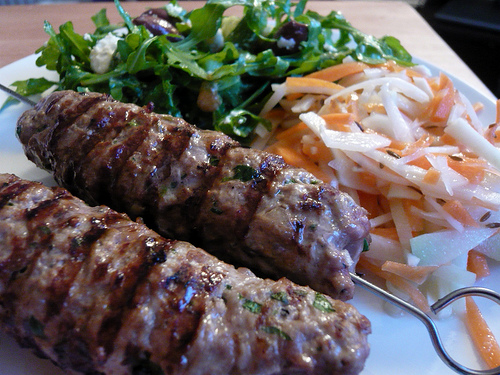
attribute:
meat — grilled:
[16, 89, 371, 299]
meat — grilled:
[0, 172, 372, 373]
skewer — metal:
[350, 273, 499, 373]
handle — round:
[429, 285, 499, 374]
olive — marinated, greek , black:
[132, 5, 183, 35]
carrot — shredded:
[284, 74, 342, 95]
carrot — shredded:
[308, 60, 368, 81]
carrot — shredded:
[274, 111, 353, 141]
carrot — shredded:
[421, 70, 456, 126]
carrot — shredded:
[441, 196, 474, 225]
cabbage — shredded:
[322, 76, 428, 103]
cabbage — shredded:
[378, 82, 412, 146]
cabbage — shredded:
[444, 116, 499, 171]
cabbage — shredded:
[329, 155, 377, 193]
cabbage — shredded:
[410, 227, 499, 268]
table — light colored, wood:
[0, 0, 496, 103]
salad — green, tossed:
[1, 0, 411, 138]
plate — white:
[0, 26, 499, 373]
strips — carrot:
[312, 93, 458, 219]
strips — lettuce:
[124, 13, 251, 76]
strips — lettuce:
[150, 25, 310, 78]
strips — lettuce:
[131, 32, 254, 82]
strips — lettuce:
[119, 15, 308, 107]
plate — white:
[22, 12, 484, 359]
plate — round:
[4, 9, 446, 372]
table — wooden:
[11, 2, 86, 52]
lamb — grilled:
[43, 96, 337, 293]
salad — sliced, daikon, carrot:
[237, 51, 465, 222]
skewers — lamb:
[5, 69, 484, 361]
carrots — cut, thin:
[303, 77, 476, 223]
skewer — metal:
[0, 58, 448, 372]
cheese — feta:
[78, 22, 162, 88]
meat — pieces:
[0, 67, 310, 371]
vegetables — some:
[304, 41, 484, 202]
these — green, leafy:
[88, 15, 238, 97]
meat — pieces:
[33, 84, 374, 370]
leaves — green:
[119, 6, 290, 97]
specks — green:
[226, 257, 359, 349]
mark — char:
[73, 190, 273, 327]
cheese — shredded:
[302, 85, 480, 240]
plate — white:
[1, 31, 467, 364]